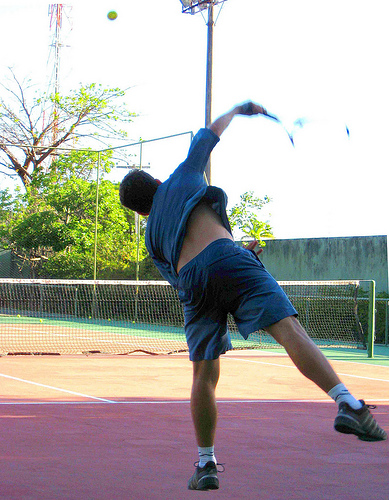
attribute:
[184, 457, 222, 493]
shoe — black and silver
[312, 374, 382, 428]
socks — white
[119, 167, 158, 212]
hair — black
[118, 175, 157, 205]
hair — dark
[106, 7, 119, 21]
ball — tennis, round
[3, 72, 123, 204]
tree — green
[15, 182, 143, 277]
tree — green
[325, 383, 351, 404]
sock — white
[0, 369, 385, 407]
lines — white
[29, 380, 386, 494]
court — red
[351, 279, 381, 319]
pole — green, metallic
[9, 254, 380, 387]
net — tennis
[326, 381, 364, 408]
sock — white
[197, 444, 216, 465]
sock — white